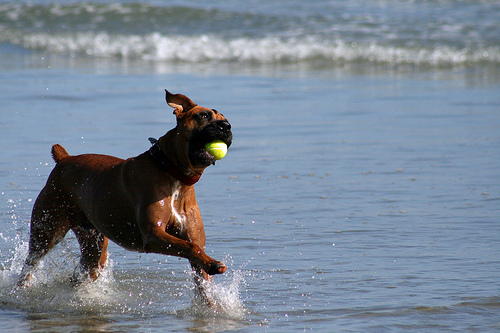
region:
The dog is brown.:
[3, 75, 264, 332]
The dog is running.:
[11, 73, 290, 325]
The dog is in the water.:
[8, 82, 429, 329]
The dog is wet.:
[7, 73, 306, 331]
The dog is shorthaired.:
[6, 75, 313, 332]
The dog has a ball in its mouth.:
[7, 60, 312, 331]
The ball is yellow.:
[9, 76, 267, 322]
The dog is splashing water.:
[1, 34, 318, 331]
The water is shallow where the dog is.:
[2, 0, 495, 329]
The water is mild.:
[1, 0, 498, 332]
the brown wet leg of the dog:
[19, 190, 69, 292]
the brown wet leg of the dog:
[68, 223, 107, 287]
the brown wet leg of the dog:
[102, 207, 224, 277]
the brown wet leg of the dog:
[179, 203, 215, 310]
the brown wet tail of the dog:
[50, 141, 70, 166]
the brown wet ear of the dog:
[164, 88, 191, 112]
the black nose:
[217, 120, 229, 133]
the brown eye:
[200, 110, 212, 122]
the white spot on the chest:
[169, 176, 191, 234]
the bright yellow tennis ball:
[206, 141, 228, 157]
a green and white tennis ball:
[202, 138, 227, 173]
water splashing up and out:
[209, 286, 277, 321]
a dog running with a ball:
[7, 89, 249, 311]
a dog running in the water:
[2, 80, 258, 318]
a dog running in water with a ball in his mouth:
[19, 78, 250, 323]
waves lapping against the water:
[171, 8, 383, 89]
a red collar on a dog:
[136, 133, 210, 197]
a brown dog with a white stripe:
[25, 76, 252, 302]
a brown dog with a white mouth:
[64, 80, 258, 317]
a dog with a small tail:
[5, 91, 267, 321]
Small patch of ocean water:
[403, 11, 426, 37]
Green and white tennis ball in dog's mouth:
[206, 138, 230, 155]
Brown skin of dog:
[99, 171, 116, 194]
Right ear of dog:
[164, 89, 190, 111]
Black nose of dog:
[219, 120, 229, 132]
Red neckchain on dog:
[173, 160, 189, 178]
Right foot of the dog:
[187, 242, 224, 275]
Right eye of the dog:
[198, 108, 209, 120]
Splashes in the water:
[53, 277, 85, 302]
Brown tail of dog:
[52, 144, 74, 159]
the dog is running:
[18, 90, 237, 302]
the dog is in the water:
[7, 88, 241, 295]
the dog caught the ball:
[204, 135, 230, 157]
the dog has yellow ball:
[205, 142, 222, 157]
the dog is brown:
[19, 91, 238, 294]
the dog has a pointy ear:
[165, 87, 195, 113]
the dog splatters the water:
[5, 87, 283, 315]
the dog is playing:
[16, 91, 248, 308]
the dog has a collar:
[148, 135, 203, 186]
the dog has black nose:
[213, 118, 227, 130]